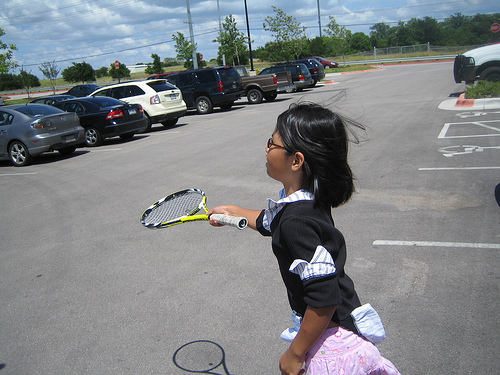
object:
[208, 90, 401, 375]
girl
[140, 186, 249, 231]
racket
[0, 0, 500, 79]
sky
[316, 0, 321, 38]
pole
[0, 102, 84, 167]
car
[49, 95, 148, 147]
car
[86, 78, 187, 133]
car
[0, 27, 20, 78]
tree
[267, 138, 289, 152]
glasses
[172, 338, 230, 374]
racket shadow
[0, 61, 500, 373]
parking lot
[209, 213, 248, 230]
white handle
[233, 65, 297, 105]
truck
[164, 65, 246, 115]
suv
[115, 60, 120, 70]
sign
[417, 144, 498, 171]
parking space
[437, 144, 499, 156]
handicapped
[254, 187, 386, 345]
shirt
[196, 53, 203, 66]
sign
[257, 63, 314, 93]
mini van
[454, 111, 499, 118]
parking space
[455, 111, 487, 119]
handicapped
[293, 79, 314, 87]
bumper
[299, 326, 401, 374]
skirt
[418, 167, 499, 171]
line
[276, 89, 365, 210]
hair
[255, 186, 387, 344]
sleeve